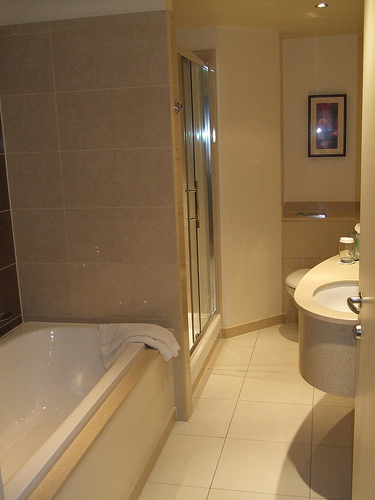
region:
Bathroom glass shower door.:
[173, 51, 232, 319]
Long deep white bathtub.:
[7, 317, 124, 496]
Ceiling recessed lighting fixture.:
[294, 0, 349, 41]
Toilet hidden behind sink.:
[273, 245, 330, 301]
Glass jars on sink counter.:
[327, 218, 361, 269]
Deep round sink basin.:
[307, 271, 360, 342]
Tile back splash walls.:
[3, 182, 179, 326]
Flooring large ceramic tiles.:
[222, 377, 355, 498]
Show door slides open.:
[181, 158, 218, 264]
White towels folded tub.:
[94, 317, 189, 380]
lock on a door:
[349, 321, 365, 342]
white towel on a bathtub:
[83, 310, 188, 379]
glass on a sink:
[335, 233, 358, 266]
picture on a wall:
[299, 86, 352, 168]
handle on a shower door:
[181, 175, 206, 235]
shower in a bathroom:
[150, 31, 249, 397]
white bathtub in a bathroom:
[1, 306, 179, 498]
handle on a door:
[342, 287, 365, 318]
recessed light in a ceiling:
[312, 0, 336, 17]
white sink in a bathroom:
[306, 273, 361, 320]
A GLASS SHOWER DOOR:
[170, 48, 224, 358]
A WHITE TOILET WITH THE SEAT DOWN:
[278, 260, 308, 302]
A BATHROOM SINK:
[287, 235, 362, 400]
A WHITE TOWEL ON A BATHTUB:
[3, 315, 185, 491]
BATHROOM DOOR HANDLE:
[342, 292, 364, 319]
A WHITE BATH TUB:
[0, 304, 175, 493]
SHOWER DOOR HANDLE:
[183, 174, 203, 231]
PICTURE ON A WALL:
[302, 85, 348, 161]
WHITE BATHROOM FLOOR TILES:
[192, 353, 315, 494]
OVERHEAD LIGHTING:
[309, 2, 333, 16]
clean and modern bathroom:
[52, 41, 325, 428]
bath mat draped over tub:
[63, 300, 198, 392]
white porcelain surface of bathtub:
[10, 306, 108, 486]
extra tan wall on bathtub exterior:
[60, 325, 173, 490]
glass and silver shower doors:
[120, 39, 255, 389]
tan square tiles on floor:
[215, 363, 320, 491]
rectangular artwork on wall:
[293, 75, 353, 183]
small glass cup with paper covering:
[321, 217, 354, 269]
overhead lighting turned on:
[277, 0, 337, 26]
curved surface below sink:
[272, 270, 362, 402]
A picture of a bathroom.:
[9, 41, 359, 485]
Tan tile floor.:
[211, 384, 318, 498]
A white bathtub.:
[6, 318, 126, 492]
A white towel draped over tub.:
[97, 308, 185, 368]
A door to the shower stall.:
[177, 53, 222, 349]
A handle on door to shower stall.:
[184, 172, 207, 233]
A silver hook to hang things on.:
[172, 95, 184, 117]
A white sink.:
[310, 267, 352, 315]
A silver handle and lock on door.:
[346, 288, 369, 337]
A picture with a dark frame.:
[300, 84, 353, 163]